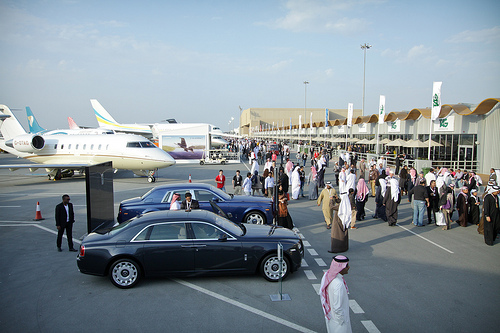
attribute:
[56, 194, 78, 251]
person — standing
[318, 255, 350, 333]
person — standing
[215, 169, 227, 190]
person — standing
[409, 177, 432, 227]
person — standing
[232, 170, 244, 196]
person — standing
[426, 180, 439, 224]
person — standing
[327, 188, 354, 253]
person — standing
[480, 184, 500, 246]
person — standing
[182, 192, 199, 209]
person — standing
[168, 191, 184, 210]
person — standing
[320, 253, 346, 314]
head covering — red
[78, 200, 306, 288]
car — black, midnight blue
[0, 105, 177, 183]
plane — white, large, jet, small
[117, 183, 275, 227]
car — blue, navy blue, parked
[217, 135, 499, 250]
people — standing, a crowd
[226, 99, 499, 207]
building — large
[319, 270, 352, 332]
clothes — white, religious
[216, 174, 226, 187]
shirt — red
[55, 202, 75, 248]
suit — black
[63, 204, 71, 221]
shirt — white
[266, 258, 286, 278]
rims — silver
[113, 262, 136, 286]
rims — silver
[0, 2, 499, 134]
sky — blue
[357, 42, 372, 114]
light pole — tall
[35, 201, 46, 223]
traffic cone — orange, white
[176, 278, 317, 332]
line — white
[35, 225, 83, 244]
line — white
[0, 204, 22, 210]
line — white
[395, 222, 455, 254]
line — white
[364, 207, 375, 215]
line — white